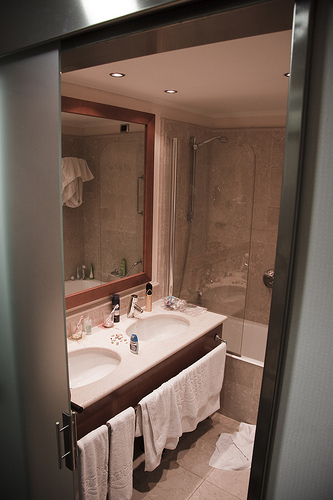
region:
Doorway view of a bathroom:
[59, 65, 259, 498]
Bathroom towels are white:
[87, 342, 235, 498]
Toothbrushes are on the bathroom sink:
[66, 297, 126, 344]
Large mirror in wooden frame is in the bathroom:
[61, 95, 158, 300]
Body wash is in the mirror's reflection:
[112, 256, 133, 278]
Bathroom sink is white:
[70, 345, 120, 385]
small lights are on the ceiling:
[111, 70, 184, 97]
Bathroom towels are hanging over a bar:
[74, 342, 237, 491]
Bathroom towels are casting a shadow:
[124, 414, 231, 497]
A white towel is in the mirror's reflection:
[59, 151, 103, 212]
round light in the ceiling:
[151, 77, 202, 104]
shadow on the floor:
[136, 456, 184, 487]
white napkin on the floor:
[212, 426, 261, 484]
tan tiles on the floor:
[177, 456, 240, 498]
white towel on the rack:
[130, 398, 200, 457]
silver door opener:
[39, 410, 78, 476]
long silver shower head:
[196, 127, 240, 161]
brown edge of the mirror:
[119, 103, 167, 179]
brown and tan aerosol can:
[134, 275, 163, 315]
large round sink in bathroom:
[117, 307, 203, 352]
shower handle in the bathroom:
[189, 131, 233, 156]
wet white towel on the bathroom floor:
[202, 420, 266, 474]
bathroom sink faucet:
[122, 295, 145, 318]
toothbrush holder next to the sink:
[70, 314, 85, 341]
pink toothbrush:
[73, 314, 86, 328]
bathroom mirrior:
[54, 101, 162, 283]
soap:
[141, 283, 158, 313]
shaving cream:
[111, 293, 122, 322]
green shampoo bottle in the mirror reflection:
[117, 257, 128, 279]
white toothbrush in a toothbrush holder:
[101, 304, 119, 327]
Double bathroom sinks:
[67, 293, 220, 410]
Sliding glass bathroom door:
[4, 34, 104, 498]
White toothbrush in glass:
[102, 300, 119, 331]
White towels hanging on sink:
[73, 339, 242, 499]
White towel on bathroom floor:
[205, 415, 256, 477]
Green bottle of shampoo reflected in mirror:
[117, 249, 127, 281]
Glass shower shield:
[161, 122, 262, 370]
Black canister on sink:
[106, 290, 125, 324]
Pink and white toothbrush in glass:
[68, 315, 88, 344]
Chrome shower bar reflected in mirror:
[128, 161, 143, 224]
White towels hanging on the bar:
[72, 343, 238, 499]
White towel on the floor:
[210, 415, 257, 470]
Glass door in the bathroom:
[0, 48, 89, 495]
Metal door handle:
[52, 411, 81, 475]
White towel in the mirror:
[60, 148, 95, 212]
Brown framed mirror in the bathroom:
[58, 92, 155, 313]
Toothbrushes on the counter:
[69, 300, 119, 341]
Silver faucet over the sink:
[125, 288, 148, 324]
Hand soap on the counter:
[81, 312, 94, 337]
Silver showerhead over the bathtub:
[188, 124, 233, 160]